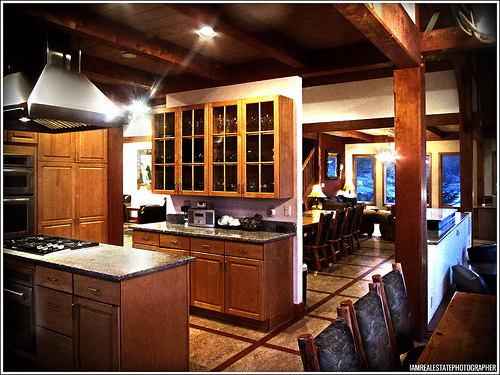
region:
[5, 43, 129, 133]
a metal range hood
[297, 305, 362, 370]
a dining room chair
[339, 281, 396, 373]
a dining room chair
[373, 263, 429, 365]
a dining room chair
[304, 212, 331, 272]
a dining room chair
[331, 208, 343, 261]
a dining room chair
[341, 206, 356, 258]
a dining room chair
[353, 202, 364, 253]
a dining room chair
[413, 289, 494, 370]
a brown dining room table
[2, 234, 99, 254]
a gas stove top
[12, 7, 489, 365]
a well appointed kitchen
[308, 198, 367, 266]
a dining room table and chairs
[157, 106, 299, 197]
a set of glass cabinets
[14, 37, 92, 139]
a hood vent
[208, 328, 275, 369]
a patterned floor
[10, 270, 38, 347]
an oven below a stovetop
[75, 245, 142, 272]
a granite counter top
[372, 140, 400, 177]
a brightly lit chandelier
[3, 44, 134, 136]
over-stove exhaust and lighting unit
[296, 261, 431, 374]
three chairs upholstered with purple print fabric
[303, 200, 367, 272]
four empty chairs in a row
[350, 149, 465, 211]
wood framed windows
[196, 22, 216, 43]
overhead ceiling light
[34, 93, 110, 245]
six large storage cabinets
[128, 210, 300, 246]
granite counter top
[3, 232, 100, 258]
stove top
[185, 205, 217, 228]
radio on countertop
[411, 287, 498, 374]
polished knotty wood table top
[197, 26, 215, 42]
a light in a ceiling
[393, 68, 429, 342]
a brown wooden post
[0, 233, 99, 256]
a black stove top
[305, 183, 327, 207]
a lamp on a table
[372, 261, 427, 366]
a wooden chair in front of a table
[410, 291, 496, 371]
a wooden dining room table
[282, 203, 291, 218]
an outlet in a wall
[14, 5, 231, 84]
a wooden beam in a ceiling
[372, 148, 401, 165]
a light hanging from a ceiling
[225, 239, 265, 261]
a kitchen drawer under a counter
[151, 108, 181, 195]
the glass door of the cabinet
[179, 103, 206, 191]
the glass door of the cabinet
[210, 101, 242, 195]
the glass door of the cabinet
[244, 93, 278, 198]
the glass door of the cabinet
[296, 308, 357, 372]
the back of the chair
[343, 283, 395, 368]
the back of the chair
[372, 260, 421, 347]
the back of the chair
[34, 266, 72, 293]
the wooden kitchen drawer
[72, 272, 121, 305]
the wooden kitchen drawer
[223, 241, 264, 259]
the wooden kitchen drawer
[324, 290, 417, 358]
cushions are on the chair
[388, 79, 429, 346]
the post is cherry wood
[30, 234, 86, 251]
stovetop is on the island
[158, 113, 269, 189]
the cabinets are see through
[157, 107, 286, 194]
glass is on the cabinets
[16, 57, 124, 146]
overhead is over the stove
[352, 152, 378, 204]
scenery outside of window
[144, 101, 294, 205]
brown wooden cabinet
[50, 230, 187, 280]
black stone countertop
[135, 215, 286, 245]
black stone countertop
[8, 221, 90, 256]
black stove top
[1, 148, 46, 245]
silver oven on wall